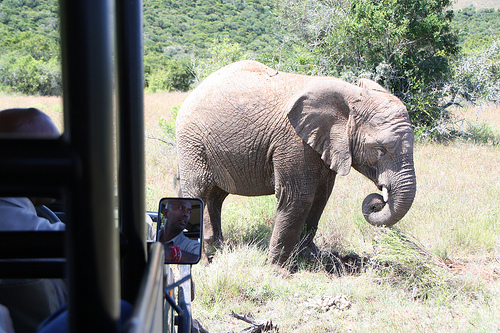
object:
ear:
[287, 83, 353, 176]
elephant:
[172, 59, 417, 270]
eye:
[372, 146, 386, 156]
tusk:
[381, 186, 390, 202]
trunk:
[362, 174, 420, 229]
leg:
[267, 158, 314, 275]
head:
[340, 78, 416, 228]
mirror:
[155, 197, 204, 265]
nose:
[183, 210, 188, 217]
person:
[157, 199, 199, 262]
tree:
[320, 0, 461, 127]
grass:
[213, 263, 498, 332]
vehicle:
[0, 0, 204, 332]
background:
[0, 1, 499, 322]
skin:
[178, 60, 327, 259]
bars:
[68, 0, 148, 330]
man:
[1, 107, 66, 333]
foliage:
[3, 1, 498, 110]